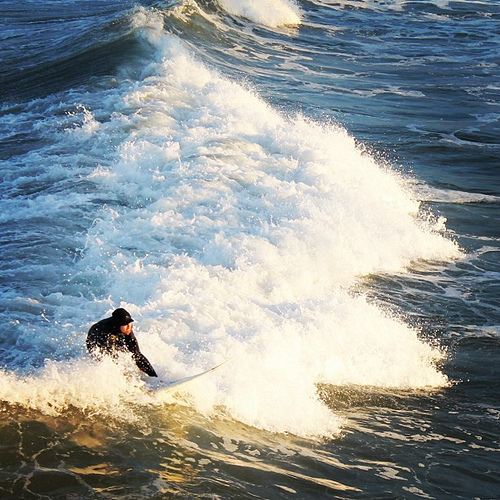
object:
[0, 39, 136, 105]
giraffe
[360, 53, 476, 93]
water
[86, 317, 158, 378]
wetsuit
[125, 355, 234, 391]
surfboard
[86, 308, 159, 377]
surfer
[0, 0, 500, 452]
wave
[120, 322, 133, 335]
face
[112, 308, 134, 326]
cap